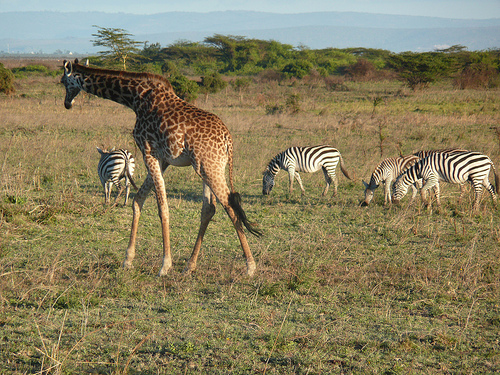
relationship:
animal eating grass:
[261, 145, 355, 198] [7, 91, 495, 372]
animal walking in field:
[60, 58, 262, 278] [0, 60, 497, 372]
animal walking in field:
[60, 58, 262, 278] [53, 152, 352, 336]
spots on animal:
[150, 103, 182, 138] [60, 58, 262, 278]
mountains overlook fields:
[0, 0, 495, 57] [2, 54, 497, 371]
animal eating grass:
[261, 145, 355, 198] [247, 197, 308, 218]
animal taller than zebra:
[60, 58, 262, 278] [92, 141, 142, 203]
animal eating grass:
[261, 145, 355, 198] [20, 65, 498, 374]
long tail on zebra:
[339, 155, 352, 179] [394, 147, 487, 212]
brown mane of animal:
[84, 62, 156, 79] [60, 58, 262, 278]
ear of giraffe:
[61, 58, 74, 75] [25, 30, 300, 323]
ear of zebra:
[353, 178, 372, 190] [252, 140, 365, 204]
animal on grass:
[60, 58, 262, 278] [20, 65, 498, 374]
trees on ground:
[7, 38, 490, 88] [278, 218, 418, 358]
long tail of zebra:
[126, 159, 139, 191] [97, 142, 134, 206]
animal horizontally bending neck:
[60, 58, 262, 278] [67, 60, 170, 114]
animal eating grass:
[391, 151, 499, 211] [20, 65, 498, 374]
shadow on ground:
[163, 182, 202, 208] [4, 70, 498, 370]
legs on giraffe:
[122, 177, 184, 272] [54, 38, 254, 283]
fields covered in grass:
[2, 54, 497, 371] [7, 91, 495, 372]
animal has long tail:
[92, 142, 139, 210] [121, 159, 139, 194]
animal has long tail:
[56, 54, 265, 281] [222, 134, 269, 241]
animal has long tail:
[259, 142, 351, 200] [335, 150, 352, 182]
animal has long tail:
[389, 145, 499, 212] [428, 160, 446, 190]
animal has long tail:
[358, 146, 440, 209] [488, 156, 499, 198]